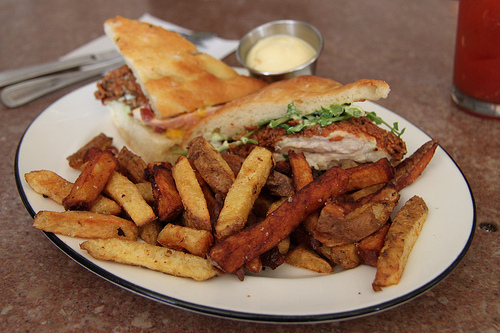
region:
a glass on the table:
[451, 6, 496, 107]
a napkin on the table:
[71, 15, 226, 65]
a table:
[5, 0, 495, 330]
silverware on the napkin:
[2, 25, 122, 95]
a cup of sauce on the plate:
[237, 17, 322, 77]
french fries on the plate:
[65, 145, 405, 255]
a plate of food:
[16, 55, 467, 315]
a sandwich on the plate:
[102, 11, 374, 157]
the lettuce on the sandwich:
[270, 95, 345, 116]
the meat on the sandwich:
[267, 118, 400, 163]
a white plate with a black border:
[12, 70, 475, 323]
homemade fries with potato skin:
[23, 132, 438, 293]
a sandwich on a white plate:
[96, 15, 403, 172]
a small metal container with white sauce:
[237, 16, 323, 77]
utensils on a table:
[3, 27, 216, 109]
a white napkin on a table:
[63, 10, 239, 77]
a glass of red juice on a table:
[451, 1, 498, 125]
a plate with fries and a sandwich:
[15, 13, 477, 320]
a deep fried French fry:
[148, 163, 181, 223]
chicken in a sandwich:
[236, 113, 406, 166]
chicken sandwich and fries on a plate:
[17, 13, 477, 315]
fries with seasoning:
[19, 104, 446, 291]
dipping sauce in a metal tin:
[231, 17, 326, 87]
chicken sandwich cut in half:
[76, 8, 403, 168]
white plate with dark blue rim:
[13, 62, 474, 326]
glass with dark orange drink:
[452, 2, 494, 125]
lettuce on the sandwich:
[209, 100, 391, 147]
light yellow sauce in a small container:
[247, 32, 314, 74]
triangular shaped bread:
[188, 74, 385, 136]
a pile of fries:
[19, 129, 456, 298]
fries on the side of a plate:
[5, 123, 478, 308]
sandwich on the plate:
[88, 13, 428, 183]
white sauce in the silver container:
[236, 14, 336, 88]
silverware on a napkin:
[2, 2, 249, 117]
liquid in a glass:
[448, 2, 499, 120]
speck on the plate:
[243, 290, 255, 297]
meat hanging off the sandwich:
[91, 60, 142, 109]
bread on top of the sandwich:
[86, 8, 402, 144]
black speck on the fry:
[120, 188, 129, 201]